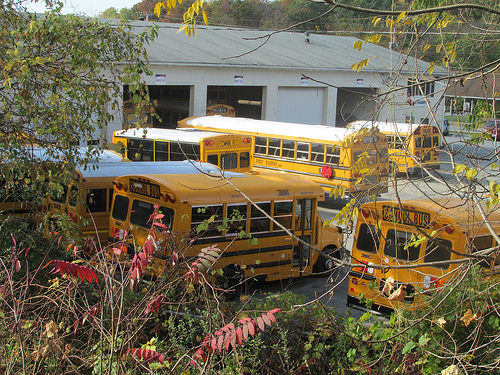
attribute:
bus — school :
[110, 171, 342, 281]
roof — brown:
[452, 68, 497, 103]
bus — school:
[179, 110, 390, 201]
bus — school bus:
[167, 82, 432, 265]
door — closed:
[290, 197, 315, 270]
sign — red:
[318, 161, 333, 183]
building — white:
[14, 7, 444, 182]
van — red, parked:
[475, 115, 497, 140]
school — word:
[45, 15, 499, 321]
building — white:
[4, 20, 451, 155]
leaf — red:
[205, 307, 281, 354]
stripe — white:
[131, 181, 144, 187]